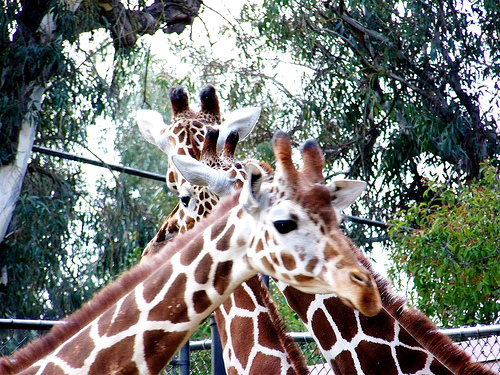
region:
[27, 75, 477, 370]
three giraffes behind a fence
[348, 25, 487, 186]
the trees with green leaves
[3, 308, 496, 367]
the chain link fence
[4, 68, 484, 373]
the giraffes are spotted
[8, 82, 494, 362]
the spots are brown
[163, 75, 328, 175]
the ossicones on the heads of the giraffe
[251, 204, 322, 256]
the eye of the giraffe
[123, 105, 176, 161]
the ear of the giraffe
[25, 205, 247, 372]
the neck of the giraffe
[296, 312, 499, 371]
the neck of the giraffe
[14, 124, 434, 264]
a green metal bar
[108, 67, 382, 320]
three giraffs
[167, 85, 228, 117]
a giraffe's ossicones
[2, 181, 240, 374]
a fuzzy maine on a giraffe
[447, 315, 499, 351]
a green chain linked fence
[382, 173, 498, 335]
a green bush with red berries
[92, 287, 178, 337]
brown spots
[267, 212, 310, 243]
a black eye of a giraffe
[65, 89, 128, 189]
sun light shinning through trees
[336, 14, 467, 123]
bent tree branches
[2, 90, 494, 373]
group of three giraffes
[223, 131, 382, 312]
face of giraffe in the front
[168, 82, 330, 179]
horns of all the giraffes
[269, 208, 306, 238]
eye of giraffe in front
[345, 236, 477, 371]
short hair mane of giraffe on the right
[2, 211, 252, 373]
neck of giraffe in the foreground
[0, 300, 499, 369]
chainlink fence and fenceposts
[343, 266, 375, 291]
nostril of giraffe in foreground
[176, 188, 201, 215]
eye of giraffe in the middle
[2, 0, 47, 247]
tree trunk of tree on left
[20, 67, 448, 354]
There are three giraffes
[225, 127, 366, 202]
The giraffe has horns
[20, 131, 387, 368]
The giraffe has spots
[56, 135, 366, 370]
The spots are brown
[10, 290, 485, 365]
The gate is grey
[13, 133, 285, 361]
The giraffe has a short mane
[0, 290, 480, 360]
A fence behind giraffes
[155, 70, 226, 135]
The horns are black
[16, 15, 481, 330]
Trees behind the giraffes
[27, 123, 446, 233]
The wire is black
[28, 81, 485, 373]
three giraffes in the enclosure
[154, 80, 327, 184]
the ossicones on the head of the giraffes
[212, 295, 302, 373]
the neck of the giraffe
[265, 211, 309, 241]
the eye of the giraffe